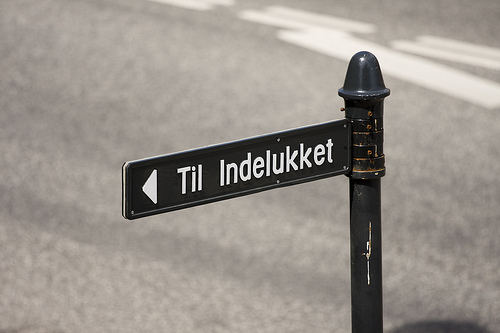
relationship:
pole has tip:
[328, 46, 398, 331] [332, 46, 393, 102]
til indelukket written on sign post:
[135, 126, 335, 221] [108, 49, 400, 327]